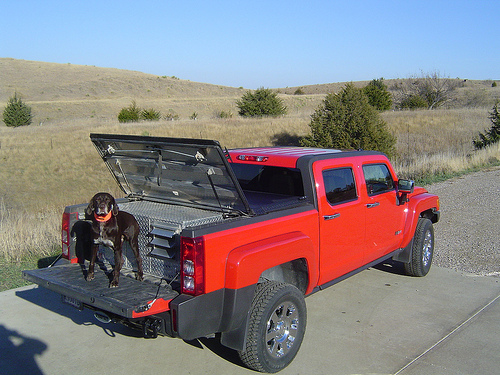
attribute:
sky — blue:
[170, 23, 259, 65]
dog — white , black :
[82, 176, 147, 286]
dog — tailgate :
[73, 194, 168, 291]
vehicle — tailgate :
[29, 244, 171, 341]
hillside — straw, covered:
[5, 52, 246, 127]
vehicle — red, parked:
[83, 139, 445, 354]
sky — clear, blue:
[40, 13, 482, 90]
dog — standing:
[64, 188, 156, 286]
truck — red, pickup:
[29, 128, 450, 359]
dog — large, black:
[77, 194, 179, 316]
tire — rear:
[230, 276, 321, 370]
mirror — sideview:
[387, 166, 419, 202]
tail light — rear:
[167, 224, 216, 314]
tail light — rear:
[42, 200, 77, 259]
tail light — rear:
[222, 147, 273, 175]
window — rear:
[208, 145, 311, 226]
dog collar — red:
[83, 208, 126, 224]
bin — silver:
[96, 197, 218, 288]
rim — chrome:
[248, 300, 313, 351]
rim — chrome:
[415, 215, 439, 264]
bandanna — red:
[85, 210, 124, 230]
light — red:
[164, 231, 222, 305]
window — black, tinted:
[305, 167, 362, 216]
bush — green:
[5, 90, 40, 123]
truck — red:
[88, 147, 409, 327]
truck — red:
[113, 147, 486, 362]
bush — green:
[105, 100, 185, 139]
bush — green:
[227, 81, 288, 121]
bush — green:
[306, 90, 392, 159]